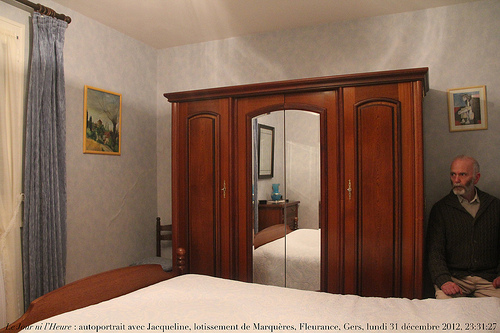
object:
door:
[342, 80, 423, 299]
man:
[428, 154, 500, 299]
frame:
[83, 84, 123, 155]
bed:
[254, 224, 321, 291]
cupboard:
[159, 67, 429, 299]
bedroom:
[0, 2, 500, 330]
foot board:
[3, 264, 177, 333]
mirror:
[251, 109, 321, 292]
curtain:
[23, 10, 68, 313]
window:
[2, 19, 22, 304]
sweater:
[428, 186, 500, 290]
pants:
[435, 276, 498, 299]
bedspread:
[19, 273, 500, 332]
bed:
[2, 264, 500, 333]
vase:
[271, 183, 281, 201]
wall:
[0, 0, 500, 284]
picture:
[447, 85, 488, 132]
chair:
[127, 215, 175, 274]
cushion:
[129, 255, 172, 271]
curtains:
[0, 15, 29, 328]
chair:
[433, 278, 490, 330]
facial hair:
[451, 179, 474, 195]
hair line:
[455, 154, 480, 177]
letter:
[58, 320, 138, 330]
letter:
[23, 322, 497, 332]